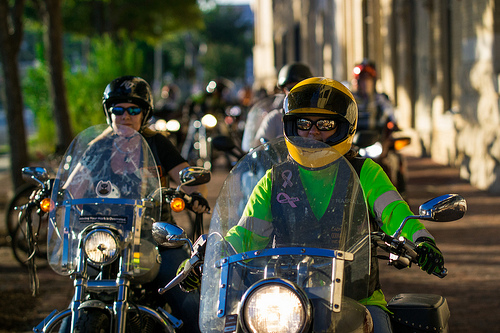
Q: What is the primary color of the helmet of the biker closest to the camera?
A: Yellow.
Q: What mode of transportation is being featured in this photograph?
A: Motorcycles.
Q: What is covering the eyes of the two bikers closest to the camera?
A: Sunglasses.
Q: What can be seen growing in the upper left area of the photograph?
A: Trees.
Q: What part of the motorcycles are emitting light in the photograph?
A: The headlights.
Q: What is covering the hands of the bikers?
A: Gloves.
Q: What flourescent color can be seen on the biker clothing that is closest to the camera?
A: Green.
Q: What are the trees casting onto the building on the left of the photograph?
A: Shadows.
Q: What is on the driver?
A: A green shirt.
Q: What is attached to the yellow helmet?
A: A clear visor.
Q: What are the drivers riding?
A: Bikes.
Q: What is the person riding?
A: A motorcycle.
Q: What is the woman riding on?
A: A motorcycle.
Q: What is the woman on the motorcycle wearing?
A: A helmet.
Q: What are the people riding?
A: Motorcycles.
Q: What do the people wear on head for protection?
A: Helmets.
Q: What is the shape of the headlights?
A: Circle.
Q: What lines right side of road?
A: Buildings.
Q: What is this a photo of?
A: Motorcycle rally.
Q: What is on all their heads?
A: Helmets.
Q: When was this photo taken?
A: Daytime.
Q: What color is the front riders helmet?
A: Yellow.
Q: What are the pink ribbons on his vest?
A: Breast cancer awareness.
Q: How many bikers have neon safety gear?
A: 1.